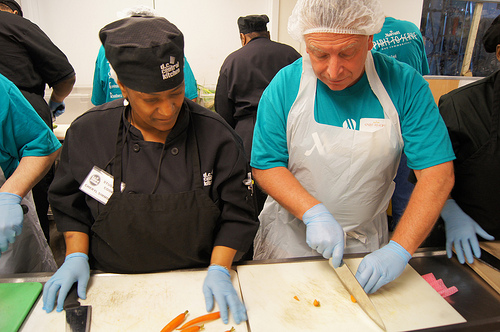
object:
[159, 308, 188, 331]
carrot slice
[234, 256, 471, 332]
carrot paper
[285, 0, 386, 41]
hair net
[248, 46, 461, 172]
shirt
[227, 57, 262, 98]
fabric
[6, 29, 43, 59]
fabric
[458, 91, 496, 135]
fabric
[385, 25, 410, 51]
fabric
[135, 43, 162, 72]
fabric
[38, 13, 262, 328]
woman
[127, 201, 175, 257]
black fabric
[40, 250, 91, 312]
blue glove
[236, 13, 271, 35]
cap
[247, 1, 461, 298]
man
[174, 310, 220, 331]
carrots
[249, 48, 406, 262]
apron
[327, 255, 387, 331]
chef's knife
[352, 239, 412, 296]
hand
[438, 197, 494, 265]
glove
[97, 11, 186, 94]
hat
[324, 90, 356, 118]
fabric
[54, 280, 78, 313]
finger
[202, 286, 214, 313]
finger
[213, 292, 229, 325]
finger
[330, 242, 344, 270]
finger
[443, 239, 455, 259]
finger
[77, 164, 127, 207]
white tag